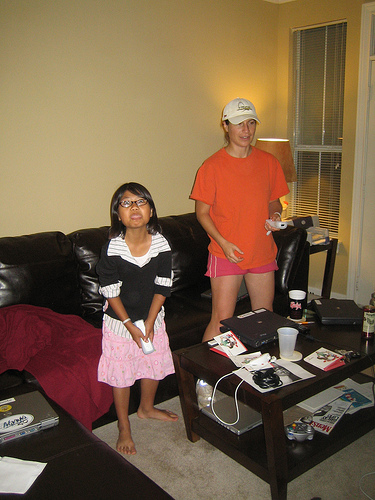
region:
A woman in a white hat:
[209, 97, 269, 150]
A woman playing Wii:
[184, 97, 305, 289]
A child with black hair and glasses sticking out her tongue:
[105, 177, 167, 245]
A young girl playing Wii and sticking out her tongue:
[95, 171, 180, 446]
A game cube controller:
[286, 420, 319, 450]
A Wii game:
[210, 329, 248, 363]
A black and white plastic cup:
[287, 288, 308, 322]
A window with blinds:
[280, 19, 351, 242]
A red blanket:
[5, 300, 112, 416]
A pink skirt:
[100, 314, 177, 390]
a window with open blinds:
[279, 37, 367, 180]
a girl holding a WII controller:
[76, 174, 189, 439]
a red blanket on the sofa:
[5, 299, 115, 425]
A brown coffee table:
[176, 299, 369, 492]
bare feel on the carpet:
[103, 405, 183, 460]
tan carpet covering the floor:
[152, 441, 223, 487]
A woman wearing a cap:
[203, 84, 273, 166]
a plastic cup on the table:
[262, 323, 312, 366]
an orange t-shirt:
[187, 139, 309, 269]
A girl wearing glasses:
[84, 182, 185, 263]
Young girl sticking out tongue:
[94, 181, 177, 454]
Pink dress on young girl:
[94, 322, 173, 384]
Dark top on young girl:
[99, 250, 170, 322]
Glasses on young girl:
[114, 196, 145, 206]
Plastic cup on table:
[274, 324, 297, 358]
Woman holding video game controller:
[187, 95, 289, 339]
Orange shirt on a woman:
[187, 150, 286, 267]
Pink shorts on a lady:
[200, 252, 280, 276]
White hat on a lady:
[218, 95, 259, 125]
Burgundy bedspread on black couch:
[1, 302, 113, 430]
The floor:
[147, 462, 163, 471]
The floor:
[185, 468, 201, 499]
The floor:
[196, 443, 224, 492]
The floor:
[182, 437, 210, 492]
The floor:
[191, 459, 215, 494]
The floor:
[173, 437, 197, 482]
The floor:
[156, 414, 216, 497]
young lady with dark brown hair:
[84, 163, 181, 452]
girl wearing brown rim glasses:
[63, 166, 181, 430]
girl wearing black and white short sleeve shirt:
[70, 225, 170, 363]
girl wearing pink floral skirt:
[68, 285, 183, 416]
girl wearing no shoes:
[91, 165, 202, 463]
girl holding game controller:
[105, 155, 177, 433]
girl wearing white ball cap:
[198, 86, 319, 326]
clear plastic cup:
[251, 311, 323, 400]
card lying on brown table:
[303, 336, 349, 380]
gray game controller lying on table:
[264, 414, 325, 459]